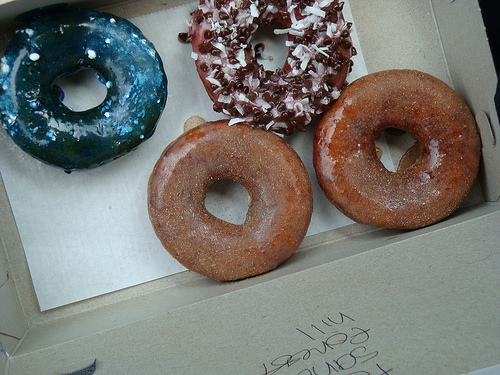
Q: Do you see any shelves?
A: No, there are no shelves.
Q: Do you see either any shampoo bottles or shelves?
A: No, there are no shelves or shampoo bottles.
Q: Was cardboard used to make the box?
A: Yes, the box is made of cardboard.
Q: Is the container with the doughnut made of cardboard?
A: Yes, the box is made of cardboard.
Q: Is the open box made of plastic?
A: No, the box is made of cardboard.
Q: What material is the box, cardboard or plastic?
A: The box is made of cardboard.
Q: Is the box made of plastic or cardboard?
A: The box is made of cardboard.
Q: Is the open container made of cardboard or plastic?
A: The box is made of cardboard.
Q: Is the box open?
A: Yes, the box is open.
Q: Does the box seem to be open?
A: Yes, the box is open.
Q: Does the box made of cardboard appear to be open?
A: Yes, the box is open.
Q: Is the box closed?
A: No, the box is open.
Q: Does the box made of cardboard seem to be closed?
A: No, the box is open.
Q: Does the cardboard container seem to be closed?
A: No, the box is open.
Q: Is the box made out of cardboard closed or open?
A: The box is open.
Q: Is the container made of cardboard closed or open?
A: The box is open.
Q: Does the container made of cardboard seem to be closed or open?
A: The box is open.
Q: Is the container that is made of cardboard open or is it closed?
A: The box is open.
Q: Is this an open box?
A: Yes, this is an open box.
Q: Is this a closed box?
A: No, this is an open box.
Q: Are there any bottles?
A: No, there are no bottles.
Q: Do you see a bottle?
A: No, there are no bottles.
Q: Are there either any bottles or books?
A: No, there are no bottles or books.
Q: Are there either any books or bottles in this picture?
A: No, there are no bottles or books.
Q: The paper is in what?
A: The paper is in the box.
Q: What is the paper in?
A: The paper is in the box.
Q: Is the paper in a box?
A: Yes, the paper is in a box.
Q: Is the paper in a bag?
A: No, the paper is in a box.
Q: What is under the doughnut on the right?
A: The paper is under the donut.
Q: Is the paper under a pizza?
A: No, the paper is under a donut.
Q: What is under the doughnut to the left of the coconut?
A: The paper is under the donut.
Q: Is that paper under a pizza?
A: No, the paper is under the doughnut.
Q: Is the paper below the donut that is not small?
A: Yes, the paper is below the donut.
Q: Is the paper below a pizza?
A: No, the paper is below the donut.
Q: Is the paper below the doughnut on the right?
A: Yes, the paper is below the donut.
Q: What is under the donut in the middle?
A: The paper is under the doughnut.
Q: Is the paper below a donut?
A: Yes, the paper is below a donut.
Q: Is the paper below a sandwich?
A: No, the paper is below a donut.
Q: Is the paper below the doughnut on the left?
A: Yes, the paper is below the donut.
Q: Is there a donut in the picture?
A: Yes, there is a donut.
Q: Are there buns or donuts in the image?
A: Yes, there is a donut.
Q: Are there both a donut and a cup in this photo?
A: No, there is a donut but no cups.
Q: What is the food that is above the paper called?
A: The food is a donut.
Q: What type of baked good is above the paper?
A: The food is a donut.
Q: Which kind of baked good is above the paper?
A: The food is a donut.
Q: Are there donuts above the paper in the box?
A: Yes, there is a donut above the paper.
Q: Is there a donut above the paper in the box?
A: Yes, there is a donut above the paper.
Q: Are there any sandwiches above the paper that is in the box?
A: No, there is a donut above the paper.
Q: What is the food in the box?
A: The food is a donut.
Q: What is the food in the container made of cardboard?
A: The food is a donut.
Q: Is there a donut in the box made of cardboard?
A: Yes, there is a donut in the box.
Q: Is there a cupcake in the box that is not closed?
A: No, there is a donut in the box.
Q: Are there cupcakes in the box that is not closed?
A: No, there is a donut in the box.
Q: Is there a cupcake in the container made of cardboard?
A: No, there is a donut in the box.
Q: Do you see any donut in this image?
A: Yes, there is a donut.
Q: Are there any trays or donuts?
A: Yes, there is a donut.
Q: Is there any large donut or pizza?
A: Yes, there is a large donut.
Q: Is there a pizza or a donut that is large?
A: Yes, the donut is large.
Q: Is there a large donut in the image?
A: Yes, there is a large donut.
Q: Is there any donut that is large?
A: Yes, there is a donut that is large.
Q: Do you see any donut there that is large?
A: Yes, there is a donut that is large.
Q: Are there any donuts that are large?
A: Yes, there is a donut that is large.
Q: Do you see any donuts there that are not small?
A: Yes, there is a large donut.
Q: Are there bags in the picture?
A: No, there are no bags.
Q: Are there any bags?
A: No, there are no bags.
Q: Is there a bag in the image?
A: No, there are no bags.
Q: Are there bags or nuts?
A: No, there are no bags or nuts.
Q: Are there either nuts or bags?
A: No, there are no bags or nuts.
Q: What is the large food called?
A: The food is a donut.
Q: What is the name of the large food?
A: The food is a donut.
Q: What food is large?
A: The food is a donut.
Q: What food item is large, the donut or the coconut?
A: The donut is large.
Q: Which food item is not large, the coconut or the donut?
A: The coconut is not large.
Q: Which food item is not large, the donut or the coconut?
A: The coconut is not large.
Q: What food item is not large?
A: The food item is a coconut.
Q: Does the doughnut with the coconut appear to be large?
A: Yes, the donut is large.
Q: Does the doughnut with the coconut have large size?
A: Yes, the donut is large.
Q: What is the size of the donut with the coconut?
A: The donut is large.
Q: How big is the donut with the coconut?
A: The donut is large.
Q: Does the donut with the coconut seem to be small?
A: No, the donut is large.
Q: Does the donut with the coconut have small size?
A: No, the donut is large.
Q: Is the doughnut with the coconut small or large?
A: The donut is large.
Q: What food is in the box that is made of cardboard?
A: The food is a donut.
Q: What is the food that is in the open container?
A: The food is a donut.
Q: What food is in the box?
A: The food is a donut.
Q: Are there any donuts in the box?
A: Yes, there is a donut in the box.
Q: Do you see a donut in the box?
A: Yes, there is a donut in the box.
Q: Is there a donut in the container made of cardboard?
A: Yes, there is a donut in the box.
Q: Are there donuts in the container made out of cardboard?
A: Yes, there is a donut in the box.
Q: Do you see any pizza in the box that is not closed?
A: No, there is a donut in the box.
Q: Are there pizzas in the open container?
A: No, there is a donut in the box.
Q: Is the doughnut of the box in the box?
A: Yes, the doughnut is in the box.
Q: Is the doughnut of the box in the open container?
A: Yes, the doughnut is in the box.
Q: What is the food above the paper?
A: The food is a donut.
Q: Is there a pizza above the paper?
A: No, there is a donut above the paper.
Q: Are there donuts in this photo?
A: Yes, there is a donut.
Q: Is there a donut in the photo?
A: Yes, there is a donut.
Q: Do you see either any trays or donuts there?
A: Yes, there is a donut.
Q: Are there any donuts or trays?
A: Yes, there is a donut.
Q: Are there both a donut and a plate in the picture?
A: No, there is a donut but no plates.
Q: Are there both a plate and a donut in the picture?
A: No, there is a donut but no plates.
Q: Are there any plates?
A: No, there are no plates.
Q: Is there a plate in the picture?
A: No, there are no plates.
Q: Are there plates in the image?
A: No, there are no plates.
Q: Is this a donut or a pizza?
A: This is a donut.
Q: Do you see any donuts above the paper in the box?
A: Yes, there is a donut above the paper.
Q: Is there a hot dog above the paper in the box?
A: No, there is a donut above the paper.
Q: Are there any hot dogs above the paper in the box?
A: No, there is a donut above the paper.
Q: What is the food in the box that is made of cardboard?
A: The food is a donut.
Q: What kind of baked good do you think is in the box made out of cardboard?
A: The food is a donut.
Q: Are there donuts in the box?
A: Yes, there is a donut in the box.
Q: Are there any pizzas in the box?
A: No, there is a donut in the box.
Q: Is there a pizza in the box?
A: No, there is a donut in the box.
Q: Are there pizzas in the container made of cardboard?
A: No, there is a donut in the box.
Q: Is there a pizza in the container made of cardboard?
A: No, there is a donut in the box.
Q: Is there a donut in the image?
A: Yes, there is a donut.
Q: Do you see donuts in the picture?
A: Yes, there is a donut.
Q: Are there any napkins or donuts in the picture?
A: Yes, there is a donut.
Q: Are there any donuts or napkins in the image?
A: Yes, there is a donut.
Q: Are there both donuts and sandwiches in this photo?
A: No, there is a donut but no sandwiches.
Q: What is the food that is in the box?
A: The food is a donut.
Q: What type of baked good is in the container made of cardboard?
A: The food is a donut.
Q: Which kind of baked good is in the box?
A: The food is a donut.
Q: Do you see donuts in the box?
A: Yes, there is a donut in the box.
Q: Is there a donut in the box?
A: Yes, there is a donut in the box.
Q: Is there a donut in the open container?
A: Yes, there is a donut in the box.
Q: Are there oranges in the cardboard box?
A: No, there is a donut in the box.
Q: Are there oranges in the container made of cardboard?
A: No, there is a donut in the box.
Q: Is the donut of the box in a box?
A: Yes, the donut is in a box.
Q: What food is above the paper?
A: The food is a donut.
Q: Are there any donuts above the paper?
A: Yes, there is a donut above the paper.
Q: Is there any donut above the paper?
A: Yes, there is a donut above the paper.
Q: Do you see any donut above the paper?
A: Yes, there is a donut above the paper.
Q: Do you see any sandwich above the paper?
A: No, there is a donut above the paper.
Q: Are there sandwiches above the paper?
A: No, there is a donut above the paper.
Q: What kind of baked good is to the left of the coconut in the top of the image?
A: The food is a donut.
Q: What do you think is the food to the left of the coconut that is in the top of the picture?
A: The food is a donut.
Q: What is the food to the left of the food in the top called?
A: The food is a donut.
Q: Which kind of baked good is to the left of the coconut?
A: The food is a donut.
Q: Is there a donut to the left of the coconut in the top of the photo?
A: Yes, there is a donut to the left of the coconut.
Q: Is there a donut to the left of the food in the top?
A: Yes, there is a donut to the left of the coconut.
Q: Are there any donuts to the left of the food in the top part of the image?
A: Yes, there is a donut to the left of the coconut.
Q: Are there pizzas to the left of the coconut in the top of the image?
A: No, there is a donut to the left of the coconut.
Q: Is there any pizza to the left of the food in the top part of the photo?
A: No, there is a donut to the left of the coconut.